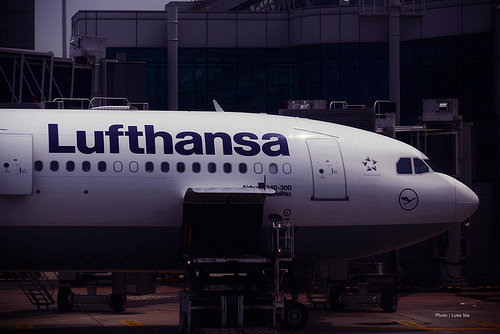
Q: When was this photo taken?
A: At night.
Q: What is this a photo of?
A: An airplane.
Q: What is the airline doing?
A: Sitting at the gate.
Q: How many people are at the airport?
A: One.